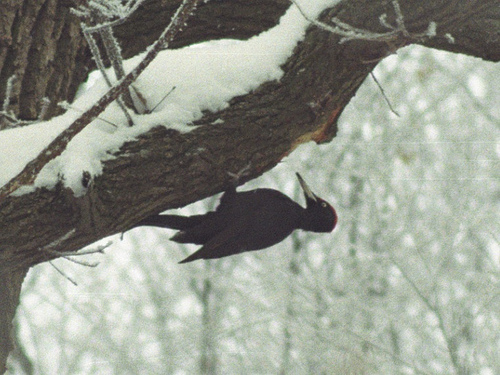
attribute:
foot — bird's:
[221, 159, 255, 183]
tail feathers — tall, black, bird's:
[138, 208, 218, 265]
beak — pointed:
[298, 167, 318, 202]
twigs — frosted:
[291, 0, 413, 47]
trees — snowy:
[11, 2, 498, 364]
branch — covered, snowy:
[0, 16, 419, 258]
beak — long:
[290, 165, 345, 232]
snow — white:
[176, 43, 279, 108]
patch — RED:
[330, 211, 339, 223]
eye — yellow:
[319, 193, 330, 213]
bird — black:
[135, 159, 338, 262]